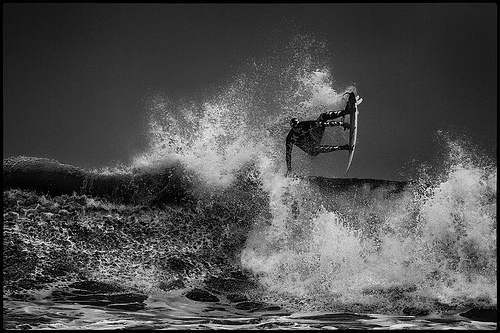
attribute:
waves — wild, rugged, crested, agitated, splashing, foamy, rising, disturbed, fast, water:
[5, 146, 494, 331]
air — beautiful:
[6, 5, 484, 179]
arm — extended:
[280, 136, 301, 180]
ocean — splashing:
[9, 227, 491, 329]